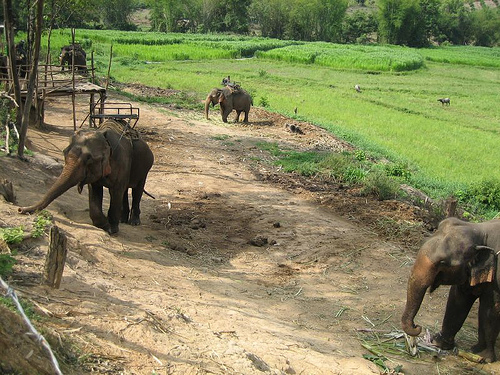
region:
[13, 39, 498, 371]
Four elephants standing in the dirt.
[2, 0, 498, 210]
Farmland in the background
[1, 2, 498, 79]
Trees lining the area.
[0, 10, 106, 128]
A small dilipitated fort.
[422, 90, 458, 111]
Farm animal in the grass.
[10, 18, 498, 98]
Thick green tall grass.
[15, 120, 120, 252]
The elephants trunk is long.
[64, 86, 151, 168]
An elephant rider seat.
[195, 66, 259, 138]
Third elephant out of four.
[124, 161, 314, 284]
An area of elephant poop.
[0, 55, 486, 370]
elephants walking in dirt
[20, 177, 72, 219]
an elephant trunk resting on the ground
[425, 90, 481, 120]
an animal standing in the grass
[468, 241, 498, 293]
a large floppy ear on the elephant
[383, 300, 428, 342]
a trunk grasping bamboo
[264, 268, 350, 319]
sticks scattered on the ground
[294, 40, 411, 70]
tall green grass growing nearby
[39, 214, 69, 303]
a large wooden stump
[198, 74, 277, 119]
an elephant with a pack on the back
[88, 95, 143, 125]
a wooden bench on the back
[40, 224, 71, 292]
brown wood sticking out of the ground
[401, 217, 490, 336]
elephant has a long trunk that is curved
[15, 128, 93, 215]
elephant's trunk is stretched out long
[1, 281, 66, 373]
part of a barbed wire fence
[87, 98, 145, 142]
saddle on the elephant's back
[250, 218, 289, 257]
big brown lumps on the ground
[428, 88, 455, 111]
small animal out in the field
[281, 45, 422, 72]
grass in the field is thick and green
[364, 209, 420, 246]
grass is dying on the ground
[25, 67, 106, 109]
open wooden deck on stilts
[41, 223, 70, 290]
A tree stump in the ground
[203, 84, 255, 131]
An elephant on the hill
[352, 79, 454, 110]
Animals in the grass field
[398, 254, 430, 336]
The trunk of the elephant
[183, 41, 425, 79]
the tall grass in the field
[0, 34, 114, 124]
A baclony made of wood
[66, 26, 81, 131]
a long tree branch on the baclony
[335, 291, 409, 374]
Grass in the girt hill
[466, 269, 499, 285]
the dirt on the elephants ear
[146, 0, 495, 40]
The trees behind the tall grass field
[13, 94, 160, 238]
The elephant has a black seat on its back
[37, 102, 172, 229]
The elephant is grey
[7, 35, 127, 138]
A platform out of sticks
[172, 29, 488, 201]
The field is green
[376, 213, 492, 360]
The elephant is eating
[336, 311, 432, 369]
Green and brown leaves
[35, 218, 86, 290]
Brown tree trunk in the dirt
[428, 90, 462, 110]
Water buffalo in the grass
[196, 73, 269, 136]
The elephant is walking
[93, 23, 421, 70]
The grass is tall